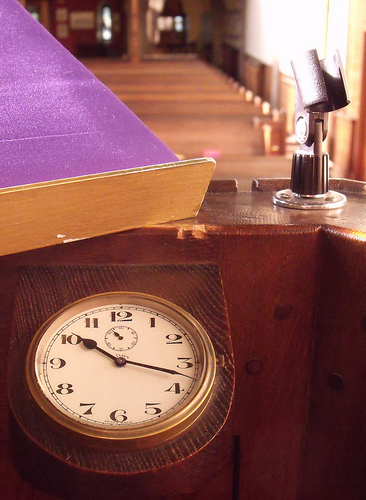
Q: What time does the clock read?
A: 10:17.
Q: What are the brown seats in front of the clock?
A: Pews.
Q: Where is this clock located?
A: A church.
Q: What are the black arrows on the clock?
A: The hands.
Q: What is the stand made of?
A: Wood.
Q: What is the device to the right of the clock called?
A: A microphone holder.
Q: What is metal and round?
A: The holder.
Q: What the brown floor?
A: Wooden.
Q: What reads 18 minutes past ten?
A: The clock.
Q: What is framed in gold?
A: The clock.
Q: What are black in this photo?
A: Clock numbers.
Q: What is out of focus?
A: The background.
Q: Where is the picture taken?
A: A hall.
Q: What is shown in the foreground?
A: A clock.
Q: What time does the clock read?
A: 10:17.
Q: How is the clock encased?
A: With wood.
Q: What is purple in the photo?
A: The lectern.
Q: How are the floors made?
A: Of wood.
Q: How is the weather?
A: Sunny.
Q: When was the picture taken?
A: Morning.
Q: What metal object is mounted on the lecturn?
A: A microphone case.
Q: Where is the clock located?
A: Under the lectern.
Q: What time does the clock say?
A: 10:18.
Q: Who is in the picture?
A: No one.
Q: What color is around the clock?
A: Gold.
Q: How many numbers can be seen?
A: 12.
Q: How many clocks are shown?
A: 1.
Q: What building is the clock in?
A: A church.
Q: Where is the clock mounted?
A: On wood.